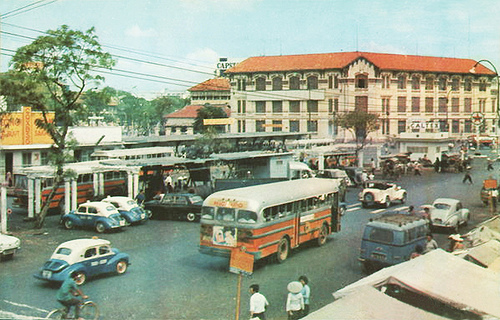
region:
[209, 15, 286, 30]
this is the sky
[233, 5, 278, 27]
the sky is blue in color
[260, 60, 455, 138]
this is a building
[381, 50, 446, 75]
this is the roof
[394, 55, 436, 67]
the roof is red in color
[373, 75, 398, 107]
this is the wall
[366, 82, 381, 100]
the wall is brown in color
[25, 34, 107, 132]
this is a tree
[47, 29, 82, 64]
the leaves are green in color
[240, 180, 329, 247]
this is a bus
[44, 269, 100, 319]
A person riding a bike.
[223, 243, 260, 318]
A sign on the street.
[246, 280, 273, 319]
A person wearing a white shirt.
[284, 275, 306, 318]
A person wearing a hat.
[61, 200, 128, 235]
A blue and white car.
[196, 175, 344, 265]
A orange bus on the street.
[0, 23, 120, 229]
A tall green tree.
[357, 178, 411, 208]
A white vehicle on the street.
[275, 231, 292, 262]
A tire on the bus.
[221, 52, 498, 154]
A building with a orange roof.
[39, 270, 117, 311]
a man riding a bike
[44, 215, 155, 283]
a car in the street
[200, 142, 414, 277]
a bus on the road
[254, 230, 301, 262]
the back wheel on a bus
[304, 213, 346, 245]
the front wheel on a bus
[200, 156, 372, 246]
the white top on a bus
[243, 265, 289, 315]
a man with a white shirt on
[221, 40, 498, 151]
a big building in the background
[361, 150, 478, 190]
prople in the background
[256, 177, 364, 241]
the side windows on a bus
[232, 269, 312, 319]
three people standing by a road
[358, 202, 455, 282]
two vehicle parked on the side of a road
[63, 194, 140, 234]
blue and white vehicles parked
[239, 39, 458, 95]
a building with a red roof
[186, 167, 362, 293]
a orange bus on a road way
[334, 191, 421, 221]
white lines painted on a street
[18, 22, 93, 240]
a tall tree by parked cars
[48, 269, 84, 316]
a man wearing a green shirt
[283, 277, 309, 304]
a person wearing a hat